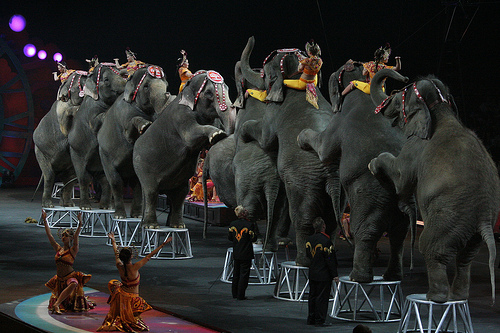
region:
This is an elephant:
[370, 61, 497, 329]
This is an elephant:
[316, 50, 407, 327]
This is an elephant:
[260, 31, 345, 308]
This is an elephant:
[225, 35, 295, 295]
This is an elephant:
[203, 56, 265, 291]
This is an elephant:
[135, 55, 237, 258]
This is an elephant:
[109, 54, 177, 246]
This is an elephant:
[70, 42, 138, 222]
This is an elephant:
[19, 58, 91, 185]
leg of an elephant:
[33, 147, 65, 199]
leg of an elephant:
[77, 167, 97, 202]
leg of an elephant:
[56, 174, 90, 204]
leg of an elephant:
[95, 177, 120, 214]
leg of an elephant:
[108, 172, 136, 220]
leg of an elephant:
[142, 188, 162, 230]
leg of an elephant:
[159, 181, 199, 230]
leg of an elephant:
[292, 202, 329, 269]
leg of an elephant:
[343, 217, 397, 282]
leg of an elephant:
[378, 215, 422, 282]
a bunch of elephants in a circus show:
[29, 33, 499, 301]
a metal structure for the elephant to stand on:
[136, 223, 197, 263]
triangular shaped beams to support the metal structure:
[333, 279, 380, 324]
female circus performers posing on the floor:
[33, 204, 178, 331]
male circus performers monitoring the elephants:
[224, 200, 344, 328]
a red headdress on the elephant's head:
[190, 68, 230, 114]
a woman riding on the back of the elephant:
[280, 40, 328, 108]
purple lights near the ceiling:
[4, 13, 64, 64]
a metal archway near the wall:
[1, 45, 40, 187]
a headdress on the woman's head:
[302, 35, 322, 57]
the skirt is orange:
[121, 303, 131, 316]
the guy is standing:
[228, 201, 250, 306]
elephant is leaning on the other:
[354, 142, 428, 201]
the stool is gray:
[351, 290, 378, 307]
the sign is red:
[207, 70, 222, 83]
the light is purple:
[11, 15, 23, 31]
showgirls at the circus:
[26, 201, 156, 331]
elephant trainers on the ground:
[220, 200, 342, 320]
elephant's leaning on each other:
[4, 57, 225, 215]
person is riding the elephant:
[280, 40, 324, 102]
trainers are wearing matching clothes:
[221, 213, 343, 318]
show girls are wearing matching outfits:
[25, 204, 157, 326]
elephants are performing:
[22, 52, 496, 292]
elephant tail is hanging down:
[486, 225, 497, 304]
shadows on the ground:
[174, 273, 265, 329]